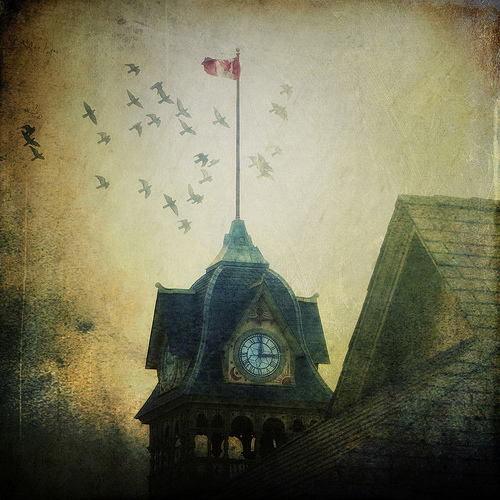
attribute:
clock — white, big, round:
[233, 326, 284, 379]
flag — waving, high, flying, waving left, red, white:
[204, 56, 240, 82]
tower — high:
[148, 34, 331, 465]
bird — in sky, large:
[165, 194, 179, 215]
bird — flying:
[93, 178, 111, 191]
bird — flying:
[28, 146, 44, 163]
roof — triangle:
[205, 220, 265, 267]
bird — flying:
[81, 101, 103, 124]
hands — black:
[257, 338, 275, 360]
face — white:
[242, 334, 278, 372]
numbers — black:
[244, 334, 280, 371]